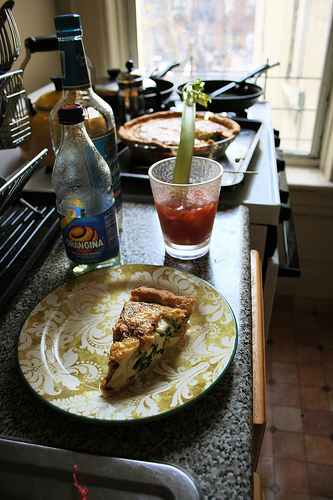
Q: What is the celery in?
A: Glass filled with red liquid.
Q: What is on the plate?
A: Slice of pie.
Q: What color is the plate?
A: Gold and white.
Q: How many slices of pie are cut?
A: One.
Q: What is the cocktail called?
A: Bloody mary.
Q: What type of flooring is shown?
A: Tile.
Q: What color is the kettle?
A: Bronze.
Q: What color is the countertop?
A: Black and grey.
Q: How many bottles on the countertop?
A: 2.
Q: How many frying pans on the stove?
A: 2.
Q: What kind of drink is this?
A: Bloody mary.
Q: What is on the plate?
A: Slice of quiche.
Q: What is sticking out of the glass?
A: Stalk of celery.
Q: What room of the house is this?
A: Kitchen.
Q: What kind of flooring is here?
A: Brown tile.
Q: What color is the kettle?
A: Yellow.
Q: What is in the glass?
A: Bloody Mary.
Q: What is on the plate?
A: Slice of quiche.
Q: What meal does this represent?
A: Brunch.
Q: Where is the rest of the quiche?
A: On top of the stove.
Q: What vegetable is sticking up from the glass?
A: Celery.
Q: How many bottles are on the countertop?
A: 2.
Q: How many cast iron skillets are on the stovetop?
A: 2.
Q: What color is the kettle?
A: Yellow.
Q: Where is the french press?
A: In the middle of the stove.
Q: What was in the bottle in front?
A: Orangina.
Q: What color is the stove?
A: White.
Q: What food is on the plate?
A: Quiche.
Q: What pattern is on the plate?
A: Paisley.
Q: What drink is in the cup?
A: Bloody mary.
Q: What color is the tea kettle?
A: Yellow.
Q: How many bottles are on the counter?
A: Two.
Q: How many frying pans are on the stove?
A: Two.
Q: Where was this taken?
A: In a kitchen.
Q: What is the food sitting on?
A: A plate.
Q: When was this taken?
A: Daytime.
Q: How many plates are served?
A: One.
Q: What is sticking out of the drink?
A: Celery.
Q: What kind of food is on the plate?
A: Quiche.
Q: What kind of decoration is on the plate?
A: Flowers.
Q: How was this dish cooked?
A: Baked.